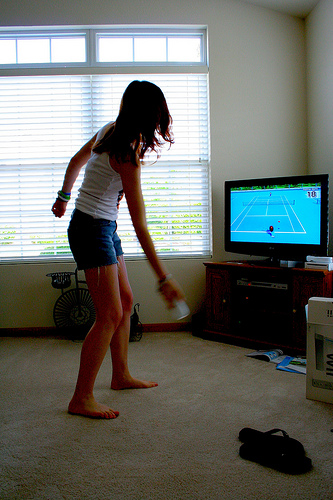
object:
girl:
[52, 78, 179, 426]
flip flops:
[240, 446, 311, 474]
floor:
[1, 324, 331, 500]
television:
[225, 177, 327, 256]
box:
[305, 298, 333, 407]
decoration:
[50, 271, 90, 335]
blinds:
[2, 73, 211, 256]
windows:
[1, 24, 210, 259]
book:
[246, 348, 286, 364]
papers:
[279, 352, 309, 372]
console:
[203, 266, 332, 339]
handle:
[173, 300, 189, 320]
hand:
[154, 275, 186, 311]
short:
[70, 211, 121, 268]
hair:
[98, 90, 172, 163]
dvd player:
[239, 271, 285, 289]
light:
[245, 280, 252, 288]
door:
[292, 275, 321, 340]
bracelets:
[57, 190, 71, 200]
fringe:
[97, 264, 100, 285]